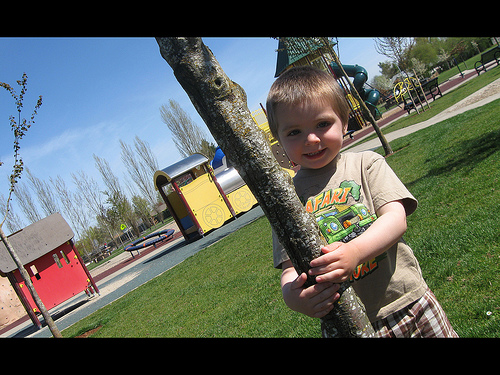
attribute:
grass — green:
[64, 35, 498, 334]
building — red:
[5, 209, 100, 338]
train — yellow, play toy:
[152, 109, 302, 239]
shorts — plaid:
[315, 278, 461, 345]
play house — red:
[2, 212, 104, 333]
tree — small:
[155, 37, 375, 335]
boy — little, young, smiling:
[261, 62, 460, 336]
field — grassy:
[47, 95, 485, 335]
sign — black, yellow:
[118, 220, 128, 231]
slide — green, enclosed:
[329, 60, 383, 121]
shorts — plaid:
[319, 289, 459, 336]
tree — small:
[0, 70, 63, 335]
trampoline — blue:
[121, 227, 175, 258]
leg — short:
[128, 250, 136, 259]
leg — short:
[134, 249, 141, 257]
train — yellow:
[150, 149, 295, 243]